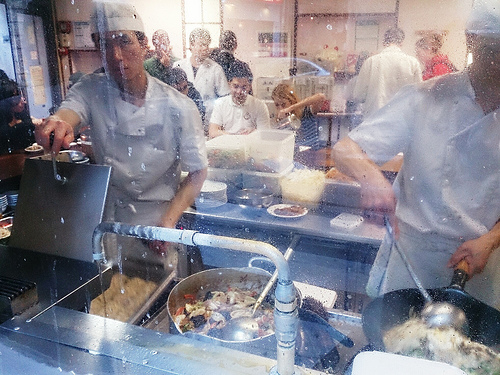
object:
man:
[34, 2, 208, 273]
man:
[330, 2, 497, 311]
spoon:
[384, 217, 470, 341]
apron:
[99, 176, 192, 277]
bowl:
[232, 177, 281, 212]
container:
[242, 126, 296, 178]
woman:
[269, 83, 328, 148]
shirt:
[295, 104, 321, 151]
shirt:
[56, 66, 210, 203]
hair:
[270, 81, 303, 124]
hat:
[90, 1, 146, 35]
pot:
[166, 266, 302, 348]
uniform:
[340, 64, 492, 248]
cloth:
[422, 54, 456, 80]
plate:
[265, 201, 309, 218]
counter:
[178, 164, 387, 249]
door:
[14, 13, 57, 118]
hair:
[226, 60, 253, 86]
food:
[383, 305, 499, 374]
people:
[171, 27, 227, 122]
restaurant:
[0, 1, 499, 235]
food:
[283, 170, 328, 210]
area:
[0, 47, 499, 182]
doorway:
[0, 0, 57, 120]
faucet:
[91, 222, 300, 373]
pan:
[363, 260, 499, 373]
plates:
[192, 181, 229, 211]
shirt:
[209, 49, 254, 96]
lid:
[11, 158, 113, 265]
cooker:
[0, 248, 499, 375]